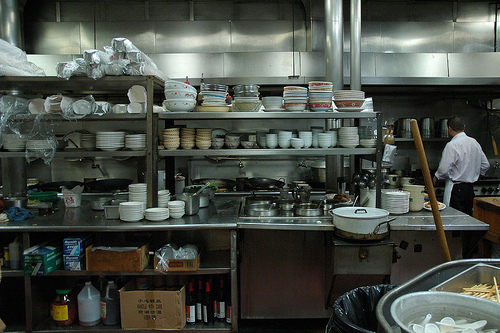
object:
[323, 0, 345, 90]
pole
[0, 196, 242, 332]
shelf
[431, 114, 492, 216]
person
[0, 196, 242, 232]
counter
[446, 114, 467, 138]
head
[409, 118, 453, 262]
mop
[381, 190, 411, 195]
plates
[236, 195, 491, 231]
countertop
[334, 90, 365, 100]
stack bowls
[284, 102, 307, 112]
stack bowls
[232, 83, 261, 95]
stack bowls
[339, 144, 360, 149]
bowls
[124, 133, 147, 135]
plates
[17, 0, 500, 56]
wall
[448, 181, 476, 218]
pants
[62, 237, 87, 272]
box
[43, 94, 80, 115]
chinese cartons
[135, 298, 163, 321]
lettering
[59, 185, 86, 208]
food carton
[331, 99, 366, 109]
bowls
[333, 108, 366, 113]
plate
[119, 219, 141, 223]
plastic cups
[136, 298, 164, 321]
writing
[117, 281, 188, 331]
box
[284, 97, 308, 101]
bowls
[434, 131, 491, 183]
white outfit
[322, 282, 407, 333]
bag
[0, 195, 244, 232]
surface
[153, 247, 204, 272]
box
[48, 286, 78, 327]
jar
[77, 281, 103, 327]
bottles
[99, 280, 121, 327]
bottles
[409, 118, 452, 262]
pole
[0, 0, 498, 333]
kitchen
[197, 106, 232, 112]
dishes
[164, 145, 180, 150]
dishes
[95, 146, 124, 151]
dishes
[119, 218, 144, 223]
dishes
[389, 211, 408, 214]
dishes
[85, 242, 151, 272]
box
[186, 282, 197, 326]
bottle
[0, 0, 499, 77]
air`s ducts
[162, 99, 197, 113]
bowls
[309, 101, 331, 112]
bowls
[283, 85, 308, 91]
bowls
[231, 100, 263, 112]
bowls